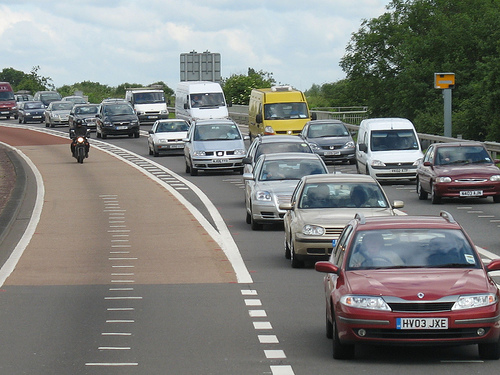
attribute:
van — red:
[0, 76, 14, 123]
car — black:
[19, 104, 48, 123]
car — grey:
[46, 101, 66, 125]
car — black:
[70, 104, 99, 133]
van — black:
[93, 101, 142, 137]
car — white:
[147, 124, 189, 153]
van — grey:
[186, 120, 245, 177]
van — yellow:
[248, 89, 311, 138]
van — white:
[174, 83, 229, 120]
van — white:
[125, 91, 167, 122]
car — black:
[302, 122, 356, 163]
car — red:
[316, 219, 498, 359]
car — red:
[421, 140, 495, 204]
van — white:
[357, 116, 421, 185]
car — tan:
[286, 184, 391, 264]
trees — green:
[375, 0, 497, 149]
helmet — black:
[74, 118, 86, 130]